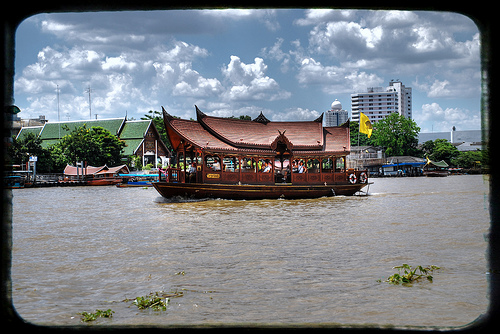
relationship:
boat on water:
[151, 104, 375, 199] [12, 175, 490, 328]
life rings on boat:
[350, 172, 367, 185] [151, 104, 375, 199]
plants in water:
[70, 258, 442, 326] [12, 175, 490, 328]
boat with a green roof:
[423, 157, 451, 179] [423, 158, 450, 169]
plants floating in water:
[70, 258, 442, 326] [12, 175, 490, 328]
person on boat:
[186, 163, 197, 182] [151, 104, 375, 199]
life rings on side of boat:
[350, 172, 367, 185] [151, 104, 375, 199]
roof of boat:
[159, 102, 353, 156] [151, 104, 375, 199]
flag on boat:
[352, 111, 382, 142] [151, 104, 375, 199]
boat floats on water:
[151, 104, 375, 199] [12, 175, 490, 328]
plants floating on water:
[70, 258, 442, 326] [12, 175, 490, 328]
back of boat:
[324, 121, 379, 194] [151, 104, 375, 199]